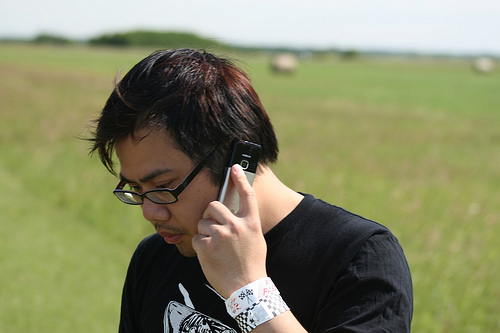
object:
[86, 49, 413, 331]
man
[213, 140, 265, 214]
cellphone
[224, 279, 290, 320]
bracelet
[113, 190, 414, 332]
shirt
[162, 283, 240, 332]
drawing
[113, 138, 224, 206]
glasses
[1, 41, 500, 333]
field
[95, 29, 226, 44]
hill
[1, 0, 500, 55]
sky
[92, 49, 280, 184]
hair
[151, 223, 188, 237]
moustache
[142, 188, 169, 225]
nose